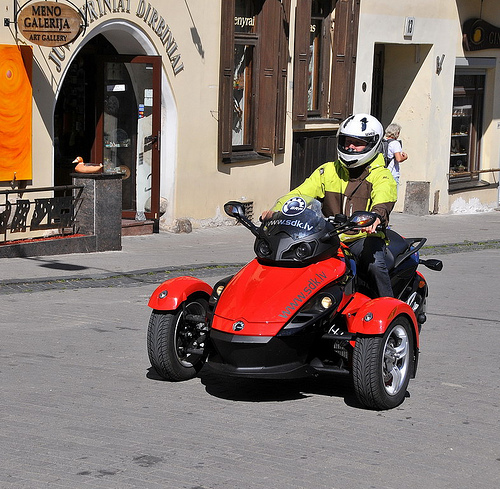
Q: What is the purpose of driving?
A: Enjoyment.